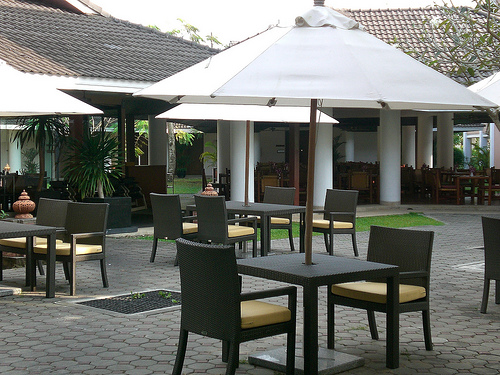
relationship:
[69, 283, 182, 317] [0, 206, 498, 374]
vent in floor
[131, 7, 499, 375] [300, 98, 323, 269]
umbrella has pole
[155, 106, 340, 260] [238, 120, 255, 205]
umbrella has pole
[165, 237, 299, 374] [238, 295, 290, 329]
chair has cushion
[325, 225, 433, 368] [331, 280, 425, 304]
chair has cushion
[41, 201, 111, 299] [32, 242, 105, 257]
chair has cushion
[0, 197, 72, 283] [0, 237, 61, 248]
chair has cushion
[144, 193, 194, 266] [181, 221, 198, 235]
chair has cushion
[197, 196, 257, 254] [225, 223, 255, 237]
chair has cushion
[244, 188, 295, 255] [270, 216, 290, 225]
chair has cushion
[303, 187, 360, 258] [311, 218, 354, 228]
chair has cushion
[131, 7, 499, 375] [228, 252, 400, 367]
umbrella above table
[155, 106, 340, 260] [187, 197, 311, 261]
umbrella above table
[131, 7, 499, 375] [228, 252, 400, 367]
umbrella shades table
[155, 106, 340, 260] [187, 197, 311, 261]
umbrella shades table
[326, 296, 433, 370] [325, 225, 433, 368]
legs on chair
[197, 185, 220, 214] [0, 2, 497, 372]
urn in cafe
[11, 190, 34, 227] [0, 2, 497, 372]
urn in cafe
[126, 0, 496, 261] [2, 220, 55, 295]
umbrella over table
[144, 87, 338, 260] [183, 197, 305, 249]
umbrella over table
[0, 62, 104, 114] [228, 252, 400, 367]
umbrella over table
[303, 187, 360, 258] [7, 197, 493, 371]
chair on patio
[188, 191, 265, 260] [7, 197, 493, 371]
chair on patio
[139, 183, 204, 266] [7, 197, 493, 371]
chair on patio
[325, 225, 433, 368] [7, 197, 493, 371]
chair on patio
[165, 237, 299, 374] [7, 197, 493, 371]
chair on patio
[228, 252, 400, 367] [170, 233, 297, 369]
table has a chair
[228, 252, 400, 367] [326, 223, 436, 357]
table has a chair